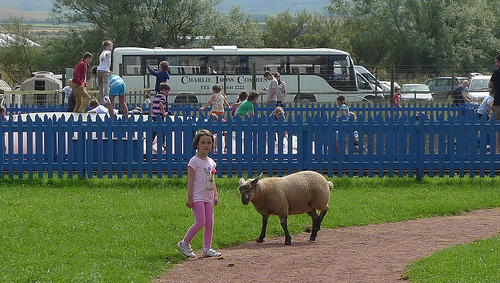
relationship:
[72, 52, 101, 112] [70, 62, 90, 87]
person wearing shirt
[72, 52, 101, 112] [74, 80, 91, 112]
person wearing khakis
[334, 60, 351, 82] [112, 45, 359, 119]
window of a bus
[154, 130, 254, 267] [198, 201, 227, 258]
girl has leg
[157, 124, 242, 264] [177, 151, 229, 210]
girl wearing pink shirt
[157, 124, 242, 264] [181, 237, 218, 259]
girl wearing sneakers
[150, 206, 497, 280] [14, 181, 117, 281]
dirt path in grass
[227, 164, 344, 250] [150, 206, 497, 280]
sheep standing on dirt path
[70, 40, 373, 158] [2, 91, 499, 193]
people standing behind fence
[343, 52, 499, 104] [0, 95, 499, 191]
parked cars behind a blue fence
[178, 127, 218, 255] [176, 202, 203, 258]
girl has leg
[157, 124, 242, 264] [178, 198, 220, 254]
girl with pants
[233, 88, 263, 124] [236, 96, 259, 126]
person with shirt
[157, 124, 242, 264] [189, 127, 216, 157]
girl has hair